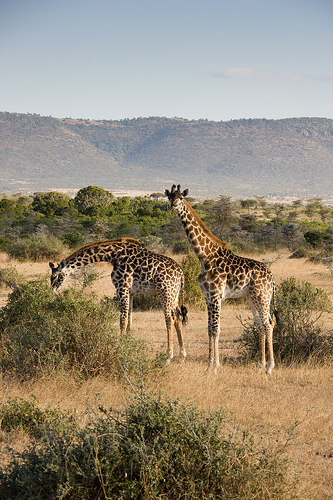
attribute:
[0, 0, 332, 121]
sky — blue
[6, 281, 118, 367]
bushes — short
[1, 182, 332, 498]
grass — tan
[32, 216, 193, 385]
giraffe — brown, spotted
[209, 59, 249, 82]
cloud — white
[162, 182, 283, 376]
spotted giraffe — brown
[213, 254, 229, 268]
spots — brown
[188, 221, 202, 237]
spots — white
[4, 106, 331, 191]
hills — rolling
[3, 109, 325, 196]
hills — bushy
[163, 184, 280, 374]
giraffe — wildlife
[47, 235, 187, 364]
giraffe — wildlife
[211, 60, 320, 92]
clouds — white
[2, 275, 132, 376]
bush — large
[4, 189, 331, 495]
prairie — African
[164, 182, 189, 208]
head — giraffe's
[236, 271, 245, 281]
spots — brown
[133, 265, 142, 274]
spots — brown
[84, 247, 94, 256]
spots — brown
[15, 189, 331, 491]
prarie — African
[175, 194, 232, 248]
mane — brown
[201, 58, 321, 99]
clouds — white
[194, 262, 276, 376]
legs — back legs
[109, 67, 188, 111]
sky — hazy